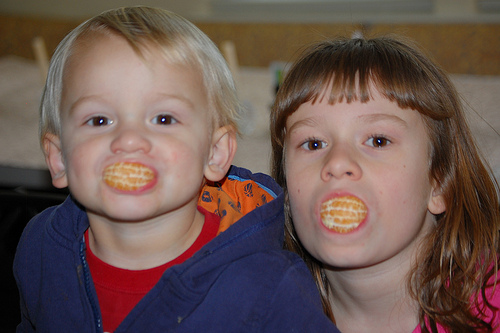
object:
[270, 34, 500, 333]
child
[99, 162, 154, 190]
orange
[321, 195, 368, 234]
orange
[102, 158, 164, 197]
mouth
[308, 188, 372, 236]
mouth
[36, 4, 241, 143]
hair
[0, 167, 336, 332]
jacket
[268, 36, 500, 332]
hair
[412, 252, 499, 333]
dress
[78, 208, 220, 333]
shirt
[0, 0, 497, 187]
wall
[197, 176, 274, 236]
lining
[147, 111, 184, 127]
eye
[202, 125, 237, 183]
ear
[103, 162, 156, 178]
piece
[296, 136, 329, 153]
eye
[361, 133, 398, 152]
eye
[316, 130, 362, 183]
nose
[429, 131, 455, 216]
ear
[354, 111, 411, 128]
eyebrow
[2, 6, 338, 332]
boy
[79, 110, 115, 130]
right eye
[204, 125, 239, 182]
left ear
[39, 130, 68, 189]
right ear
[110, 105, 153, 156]
nose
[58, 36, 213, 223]
face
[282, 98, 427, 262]
face